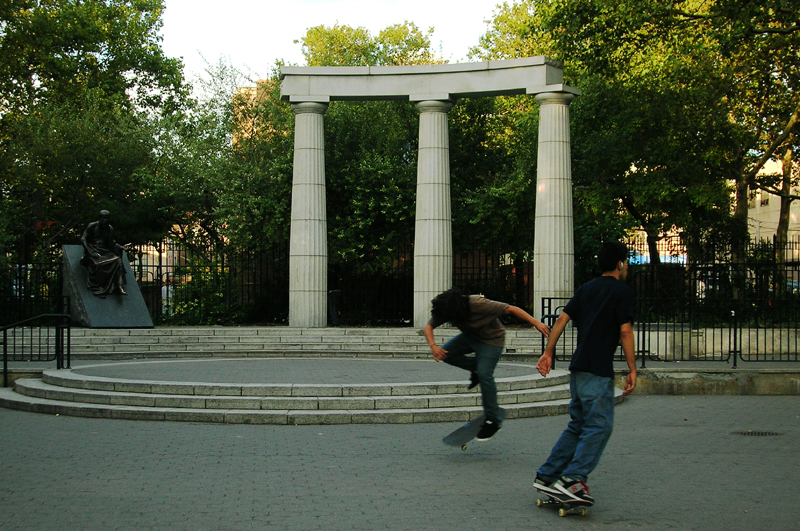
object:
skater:
[423, 290, 550, 450]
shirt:
[430, 295, 510, 348]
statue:
[81, 211, 135, 300]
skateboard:
[443, 408, 509, 451]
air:
[366, 368, 544, 465]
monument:
[62, 240, 154, 327]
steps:
[0, 357, 622, 424]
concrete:
[0, 420, 800, 529]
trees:
[4, 3, 208, 325]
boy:
[423, 290, 551, 451]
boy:
[530, 242, 636, 516]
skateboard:
[535, 487, 595, 518]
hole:
[731, 431, 789, 436]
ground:
[9, 395, 797, 529]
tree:
[0, 3, 220, 328]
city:
[6, 0, 800, 527]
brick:
[318, 328, 335, 343]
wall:
[204, 327, 384, 357]